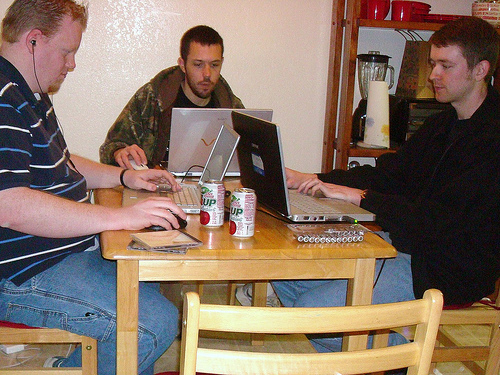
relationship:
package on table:
[289, 223, 371, 245] [94, 176, 396, 373]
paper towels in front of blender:
[355, 82, 396, 147] [351, 41, 410, 144]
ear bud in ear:
[26, 37, 45, 95] [20, 23, 57, 63]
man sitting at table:
[0, 0, 183, 373] [94, 176, 396, 373]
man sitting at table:
[102, 21, 245, 180] [94, 176, 396, 373]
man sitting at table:
[267, 12, 497, 372] [94, 176, 396, 373]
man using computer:
[267, 12, 497, 372] [230, 110, 376, 224]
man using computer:
[102, 21, 245, 180] [157, 106, 275, 176]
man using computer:
[0, 0, 183, 373] [119, 122, 240, 215]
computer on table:
[147, 103, 275, 175] [94, 176, 396, 373]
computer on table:
[227, 105, 381, 224] [94, 176, 396, 373]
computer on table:
[119, 122, 242, 212] [94, 176, 396, 373]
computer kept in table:
[119, 122, 240, 215] [94, 176, 396, 373]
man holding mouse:
[269, 16, 499, 375] [133, 191, 197, 236]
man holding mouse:
[0, 0, 188, 375] [121, 147, 153, 173]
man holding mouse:
[98, 23, 244, 171] [133, 191, 197, 236]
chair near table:
[178, 286, 448, 371] [94, 176, 396, 373]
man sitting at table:
[269, 16, 499, 375] [1, 155, 401, 373]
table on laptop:
[1, 155, 401, 373] [220, 101, 386, 243]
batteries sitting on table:
[296, 226, 410, 258] [161, 233, 415, 365]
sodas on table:
[195, 176, 258, 243] [75, 163, 415, 364]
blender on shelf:
[345, 35, 399, 155] [297, 93, 449, 190]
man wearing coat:
[267, 12, 497, 372] [317, 81, 499, 307]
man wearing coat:
[102, 21, 245, 180] [100, 67, 242, 176]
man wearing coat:
[0, 0, 183, 373] [317, 81, 499, 307]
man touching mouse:
[0, 0, 188, 375] [126, 189, 228, 269]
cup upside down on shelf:
[364, 70, 395, 162] [332, 79, 404, 164]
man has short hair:
[267, 12, 497, 372] [425, 11, 498, 83]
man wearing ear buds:
[0, 0, 183, 373] [14, 24, 70, 129]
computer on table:
[230, 110, 376, 224] [94, 176, 396, 373]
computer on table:
[230, 110, 376, 224] [86, 140, 406, 365]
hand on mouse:
[114, 183, 205, 236] [133, 204, 185, 225]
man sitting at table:
[0, 0, 183, 373] [93, 144, 394, 374]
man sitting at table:
[102, 21, 245, 180] [93, 144, 394, 374]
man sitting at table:
[267, 12, 497, 372] [93, 144, 394, 374]